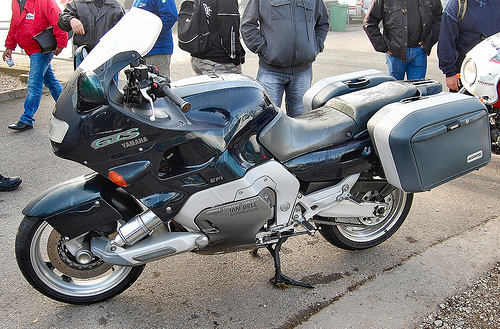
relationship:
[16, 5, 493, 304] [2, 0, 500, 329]
motorcycle in area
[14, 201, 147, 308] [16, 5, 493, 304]
wheel on motorcycle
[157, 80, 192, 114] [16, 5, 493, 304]
handle on motorcycle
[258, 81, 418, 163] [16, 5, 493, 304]
seat on motorcycle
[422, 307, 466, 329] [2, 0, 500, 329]
gravel on area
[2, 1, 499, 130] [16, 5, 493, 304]
people near motorcycle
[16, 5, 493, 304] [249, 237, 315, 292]
motorcycle has kickstand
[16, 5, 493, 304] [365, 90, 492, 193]
motorcycle has bag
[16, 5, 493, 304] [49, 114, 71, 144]
motorcycle has light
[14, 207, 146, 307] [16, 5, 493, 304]
wheel on motorcycle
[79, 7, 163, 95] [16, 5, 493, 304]
windshield on motorcycle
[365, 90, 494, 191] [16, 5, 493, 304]
bag on motorcycle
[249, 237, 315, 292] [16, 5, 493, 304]
kickstand on motorcycle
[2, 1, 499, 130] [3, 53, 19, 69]
people carrying can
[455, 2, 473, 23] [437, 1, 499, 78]
stripes on jacket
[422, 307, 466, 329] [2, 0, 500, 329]
gravel next to area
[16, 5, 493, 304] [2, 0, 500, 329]
motorcycle on area